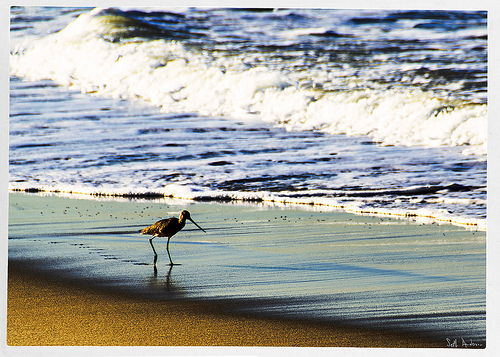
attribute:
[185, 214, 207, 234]
beak — thin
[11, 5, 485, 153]
wave — heavy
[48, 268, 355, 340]
sand — brown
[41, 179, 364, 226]
pebbles — small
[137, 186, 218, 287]
bird — long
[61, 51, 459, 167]
wave — white, breaking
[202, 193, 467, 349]
ground — slightly wet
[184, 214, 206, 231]
beak — long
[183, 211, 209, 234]
beak — sharp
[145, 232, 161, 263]
leg — thin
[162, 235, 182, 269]
leg — thin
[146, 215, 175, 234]
feathers — folded